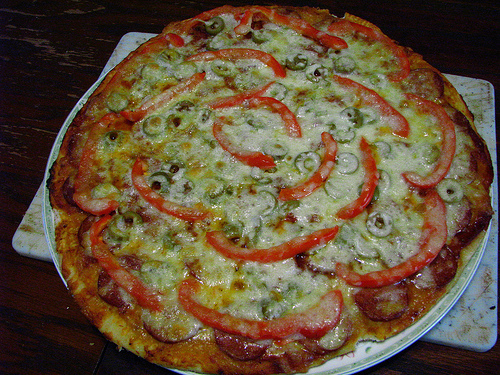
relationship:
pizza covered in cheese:
[24, 6, 485, 347] [292, 97, 327, 127]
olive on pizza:
[90, 16, 460, 318] [24, 6, 485, 347]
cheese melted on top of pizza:
[92, 16, 474, 346] [49, 6, 494, 375]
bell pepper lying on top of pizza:
[72, 8, 454, 338] [49, 6, 494, 375]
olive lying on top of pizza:
[90, 16, 460, 318] [49, 6, 494, 375]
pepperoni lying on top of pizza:
[62, 122, 478, 360] [49, 6, 494, 375]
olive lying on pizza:
[90, 16, 460, 318] [49, 6, 494, 375]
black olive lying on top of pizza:
[211, 25, 215, 29] [49, 6, 494, 375]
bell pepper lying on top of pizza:
[72, 8, 454, 338] [208, 85, 453, 212]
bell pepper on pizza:
[72, 8, 454, 338] [83, 31, 454, 373]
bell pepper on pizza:
[72, 8, 454, 338] [154, 45, 415, 282]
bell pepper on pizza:
[72, 8, 454, 338] [49, 6, 494, 375]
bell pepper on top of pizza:
[72, 8, 454, 338] [49, 6, 494, 375]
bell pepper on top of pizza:
[222, 16, 345, 62] [49, 6, 494, 375]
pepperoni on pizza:
[62, 122, 478, 360] [49, 6, 494, 375]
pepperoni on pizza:
[211, 322, 271, 361] [49, 6, 494, 375]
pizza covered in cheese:
[49, 6, 494, 375] [92, 16, 474, 346]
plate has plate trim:
[26, 4, 494, 366] [352, 344, 397, 361]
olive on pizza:
[90, 16, 460, 318] [48, 34, 478, 344]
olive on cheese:
[90, 16, 460, 318] [240, 125, 257, 145]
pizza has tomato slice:
[49, 6, 494, 375] [206, 218, 344, 268]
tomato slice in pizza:
[206, 218, 344, 268] [49, 6, 494, 375]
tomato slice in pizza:
[132, 159, 200, 226] [49, 6, 494, 375]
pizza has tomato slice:
[49, 6, 494, 375] [132, 159, 200, 226]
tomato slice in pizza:
[340, 140, 377, 217] [49, 6, 494, 375]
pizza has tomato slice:
[49, 6, 494, 375] [340, 140, 377, 217]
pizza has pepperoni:
[49, 6, 494, 375] [62, 122, 478, 360]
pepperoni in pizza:
[62, 122, 478, 360] [49, 6, 494, 375]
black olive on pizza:
[370, 212, 390, 233] [49, 6, 494, 375]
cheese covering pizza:
[92, 16, 474, 346] [49, 6, 494, 375]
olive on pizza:
[337, 150, 359, 175] [49, 6, 494, 375]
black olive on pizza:
[146, 167, 176, 197] [49, 6, 494, 375]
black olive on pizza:
[297, 63, 339, 91] [49, 6, 494, 375]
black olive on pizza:
[43, 19, 441, 341] [49, 6, 494, 375]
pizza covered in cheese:
[49, 6, 494, 375] [390, 149, 419, 175]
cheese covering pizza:
[390, 149, 419, 175] [49, 6, 494, 375]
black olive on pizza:
[201, 16, 229, 37] [49, 6, 494, 375]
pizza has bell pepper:
[49, 6, 494, 375] [72, 8, 454, 338]